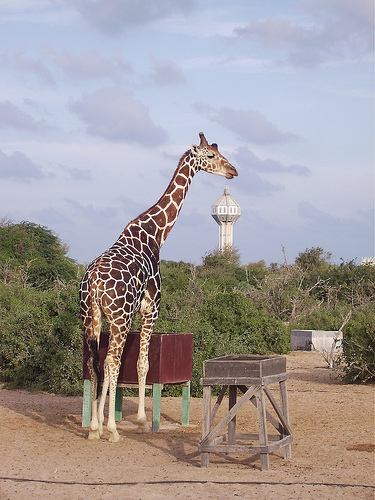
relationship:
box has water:
[84, 330, 196, 387] [86, 348, 193, 384]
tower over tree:
[213, 186, 242, 257] [0, 219, 82, 388]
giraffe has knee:
[76, 131, 241, 442] [137, 360, 151, 375]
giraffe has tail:
[76, 131, 241, 442] [77, 281, 102, 400]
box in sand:
[84, 330, 196, 387] [0, 350, 375, 499]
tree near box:
[0, 219, 82, 388] [84, 330, 196, 387]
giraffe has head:
[76, 131, 241, 442] [188, 132, 239, 181]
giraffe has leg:
[76, 131, 241, 442] [133, 276, 162, 425]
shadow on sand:
[1, 476, 374, 490] [0, 350, 375, 499]